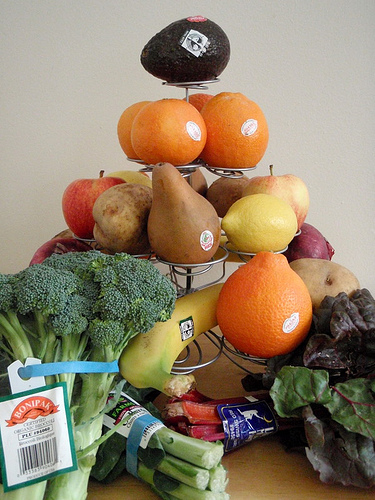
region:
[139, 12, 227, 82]
an avocado on top of a veggie pyramid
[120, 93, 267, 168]
four oranges on the pyramid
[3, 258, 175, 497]
a bunch of broccoli standing up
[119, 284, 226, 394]
a yellow bannana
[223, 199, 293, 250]
a yellow lemon.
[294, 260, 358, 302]
a white potato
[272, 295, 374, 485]
some red leaf lettuce on the right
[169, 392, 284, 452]
a bunch of rhubarb under the pyramid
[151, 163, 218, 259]
a brown colored pear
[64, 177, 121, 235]
a red apple on the left of the pyramid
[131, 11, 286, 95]
dark green avocado on top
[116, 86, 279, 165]
four oranges below avocado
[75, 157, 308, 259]
numerous fruits below oranges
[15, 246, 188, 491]
green broccoli on left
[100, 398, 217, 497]
celery next to broccoli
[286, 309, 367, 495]
dark red cabbage next to orange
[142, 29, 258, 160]
stickers on many fruits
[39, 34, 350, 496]
fruits and vegetables on brown table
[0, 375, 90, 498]
green white and orange label on broccoli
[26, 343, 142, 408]
blue rubber band around broccoli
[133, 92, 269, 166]
two side-by-side oranges with white stickers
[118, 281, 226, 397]
a single yellow banana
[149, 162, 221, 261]
a brown pear with a white sticker on the side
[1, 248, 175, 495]
green broccoli with a blue rubber band around it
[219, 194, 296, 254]
a yellow lemon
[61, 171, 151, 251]
a yellow apple, a red apple, and a brown potato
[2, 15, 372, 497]
a tier of fruit and vegetables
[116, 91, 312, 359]
five bright orange oranges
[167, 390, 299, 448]
red rhubarb with a blue sticker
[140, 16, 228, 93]
a piece of black fruit on a metal rack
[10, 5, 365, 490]
Fruits and vegetables display on a rack.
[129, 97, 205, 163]
The orange is round.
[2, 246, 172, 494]
The broccoli is standing next to the banana.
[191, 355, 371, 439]
The rhubarb is on the table.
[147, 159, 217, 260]
The pear is tan colored.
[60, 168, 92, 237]
The apple is red.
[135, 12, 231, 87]
The avocado is on top of the fruit rack.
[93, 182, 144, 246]
The potato is mixed among the fruits.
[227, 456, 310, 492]
The table is made of wood.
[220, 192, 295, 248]
The lemon is yellow.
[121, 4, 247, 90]
An avocado at the top of a fruit stand.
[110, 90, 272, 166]
Four oranges on a fruit stand.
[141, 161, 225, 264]
One pear beside a lemon.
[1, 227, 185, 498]
A bunch of broccoli beside some fruit.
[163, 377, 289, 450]
A bundle of rhubarb on a table.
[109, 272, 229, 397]
One banana beside an orange.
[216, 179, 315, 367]
A lemon above an orange.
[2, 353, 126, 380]
A blue band surrounding a bunch of broccoli.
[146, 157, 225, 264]
A round sticker on a pear.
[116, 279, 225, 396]
A square sticker on a banana.